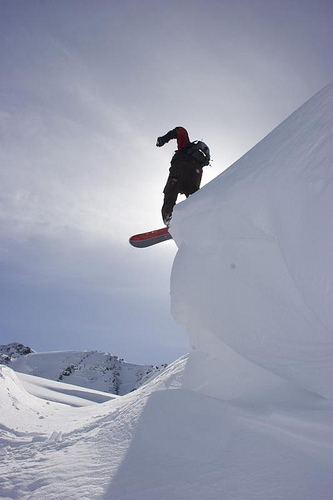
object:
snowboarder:
[119, 117, 219, 257]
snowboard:
[123, 219, 185, 260]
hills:
[2, 338, 176, 408]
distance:
[4, 192, 318, 424]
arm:
[150, 120, 192, 161]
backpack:
[172, 138, 201, 192]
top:
[128, 66, 332, 217]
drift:
[115, 75, 331, 407]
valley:
[8, 380, 127, 435]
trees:
[56, 347, 127, 394]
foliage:
[54, 351, 133, 396]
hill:
[14, 346, 169, 386]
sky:
[4, 0, 190, 345]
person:
[123, 125, 226, 263]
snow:
[3, 65, 328, 499]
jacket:
[154, 123, 225, 190]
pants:
[161, 176, 201, 229]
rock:
[1, 343, 35, 370]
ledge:
[165, 190, 222, 239]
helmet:
[195, 140, 208, 154]